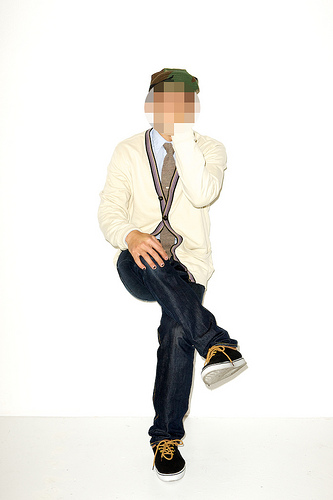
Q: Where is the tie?
A: Man's neck.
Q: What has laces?
A: Shoes.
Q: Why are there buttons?
A: To close sweater.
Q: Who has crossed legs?
A: The man.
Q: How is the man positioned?
A: Seated with crossed legs.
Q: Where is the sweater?
A: On the man's body.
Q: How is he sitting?
A: With legs crossed.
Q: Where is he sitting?
A: On his behind.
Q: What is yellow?
A: Shoestrings.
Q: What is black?
A: Shoes.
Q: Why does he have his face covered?
A: Doesn't want to be known.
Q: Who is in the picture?
A: Man.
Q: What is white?
A: Shirt.